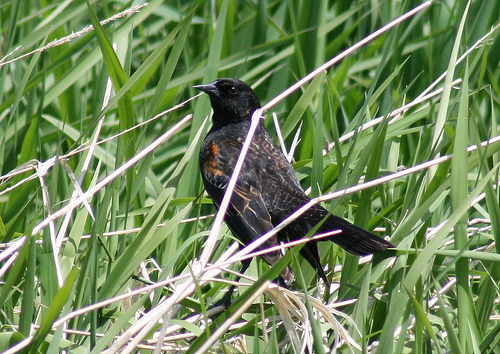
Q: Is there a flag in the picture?
A: No, there are no flags.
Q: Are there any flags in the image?
A: No, there are no flags.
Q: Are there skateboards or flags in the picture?
A: No, there are no flags or skateboards.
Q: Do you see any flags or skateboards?
A: No, there are no flags or skateboards.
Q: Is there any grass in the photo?
A: Yes, there is grass.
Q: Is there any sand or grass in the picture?
A: Yes, there is grass.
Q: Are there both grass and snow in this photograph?
A: No, there is grass but no snow.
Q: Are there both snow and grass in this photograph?
A: No, there is grass but no snow.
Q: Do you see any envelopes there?
A: No, there are no envelopes.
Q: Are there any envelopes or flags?
A: No, there are no envelopes or flags.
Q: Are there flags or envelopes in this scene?
A: No, there are no envelopes or flags.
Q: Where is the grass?
A: The grass is on the ground.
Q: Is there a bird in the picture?
A: Yes, there is a bird.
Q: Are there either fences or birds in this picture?
A: Yes, there is a bird.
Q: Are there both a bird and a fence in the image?
A: No, there is a bird but no fences.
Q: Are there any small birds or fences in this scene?
A: Yes, there is a small bird.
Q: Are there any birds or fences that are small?
A: Yes, the bird is small.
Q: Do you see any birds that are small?
A: Yes, there is a small bird.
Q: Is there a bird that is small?
A: Yes, there is a bird that is small.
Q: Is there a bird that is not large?
A: Yes, there is a small bird.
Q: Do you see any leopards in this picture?
A: No, there are no leopards.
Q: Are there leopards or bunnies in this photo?
A: No, there are no leopards or bunnies.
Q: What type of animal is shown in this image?
A: The animal is a bird.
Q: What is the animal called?
A: The animal is a bird.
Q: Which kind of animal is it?
A: The animal is a bird.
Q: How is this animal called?
A: This is a bird.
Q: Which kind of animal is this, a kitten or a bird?
A: This is a bird.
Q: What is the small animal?
A: The animal is a bird.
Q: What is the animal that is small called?
A: The animal is a bird.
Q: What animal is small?
A: The animal is a bird.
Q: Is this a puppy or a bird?
A: This is a bird.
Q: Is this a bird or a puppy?
A: This is a bird.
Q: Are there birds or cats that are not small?
A: No, there is a bird but it is small.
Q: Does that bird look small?
A: Yes, the bird is small.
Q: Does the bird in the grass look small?
A: Yes, the bird is small.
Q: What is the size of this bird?
A: The bird is small.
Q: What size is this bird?
A: The bird is small.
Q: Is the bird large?
A: No, the bird is small.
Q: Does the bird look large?
A: No, the bird is small.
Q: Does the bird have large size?
A: No, the bird is small.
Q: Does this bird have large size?
A: No, the bird is small.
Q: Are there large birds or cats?
A: No, there is a bird but it is small.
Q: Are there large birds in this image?
A: No, there is a bird but it is small.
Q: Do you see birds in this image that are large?
A: No, there is a bird but it is small.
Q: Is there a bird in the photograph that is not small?
A: No, there is a bird but it is small.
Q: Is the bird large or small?
A: The bird is small.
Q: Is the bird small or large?
A: The bird is small.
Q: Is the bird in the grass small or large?
A: The bird is small.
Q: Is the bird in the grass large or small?
A: The bird is small.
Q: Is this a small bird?
A: Yes, this is a small bird.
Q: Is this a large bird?
A: No, this is a small bird.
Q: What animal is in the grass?
A: The bird is in the grass.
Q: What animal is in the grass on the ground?
A: The animal is a bird.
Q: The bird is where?
A: The bird is in the grass.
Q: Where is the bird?
A: The bird is in the grass.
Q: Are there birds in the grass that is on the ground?
A: Yes, there is a bird in the grass.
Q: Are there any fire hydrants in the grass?
A: No, there is a bird in the grass.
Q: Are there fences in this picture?
A: No, there are no fences.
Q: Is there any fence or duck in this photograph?
A: No, there are no fences or ducks.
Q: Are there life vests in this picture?
A: No, there are no life vests.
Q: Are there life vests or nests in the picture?
A: No, there are no life vests or nests.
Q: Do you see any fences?
A: No, there are no fences.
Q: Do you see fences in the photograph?
A: No, there are no fences.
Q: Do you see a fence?
A: No, there are no fences.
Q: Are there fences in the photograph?
A: No, there are no fences.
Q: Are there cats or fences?
A: No, there are no fences or cats.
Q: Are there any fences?
A: No, there are no fences.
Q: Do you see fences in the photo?
A: No, there are no fences.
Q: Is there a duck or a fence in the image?
A: No, there are no fences or ducks.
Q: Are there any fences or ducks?
A: No, there are no fences or ducks.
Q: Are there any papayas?
A: No, there are no papayas.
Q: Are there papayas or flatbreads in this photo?
A: No, there are no papayas or flatbreads.